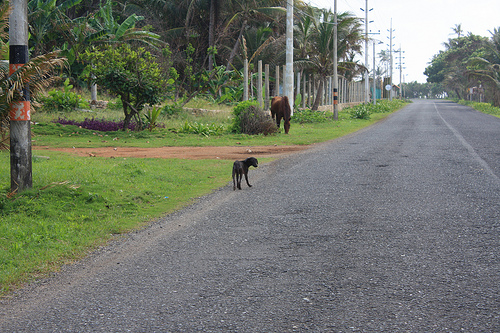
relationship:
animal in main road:
[232, 156, 258, 190] [1, 97, 500, 333]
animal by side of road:
[270, 95, 292, 134] [0, 92, 496, 328]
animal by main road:
[270, 95, 292, 134] [1, 97, 500, 333]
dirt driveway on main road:
[32, 144, 312, 159] [1, 100, 498, 330]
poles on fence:
[240, 62, 375, 122] [243, 59, 385, 114]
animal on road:
[232, 156, 258, 190] [0, 92, 496, 328]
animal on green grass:
[232, 156, 258, 190] [0, 152, 226, 298]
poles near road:
[279, 0, 340, 120] [0, 92, 496, 328]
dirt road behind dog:
[31, 126, 307, 168] [223, 149, 258, 189]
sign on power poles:
[6, 54, 33, 129] [0, 0, 406, 192]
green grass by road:
[0, 159, 228, 271] [0, 92, 496, 328]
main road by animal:
[1, 97, 500, 333] [263, 87, 295, 139]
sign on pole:
[330, 84, 340, 104] [328, 0, 343, 119]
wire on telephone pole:
[370, 2, 389, 39] [364, 0, 371, 103]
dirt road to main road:
[31, 126, 307, 168] [1, 97, 500, 333]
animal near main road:
[270, 95, 292, 134] [1, 97, 500, 333]